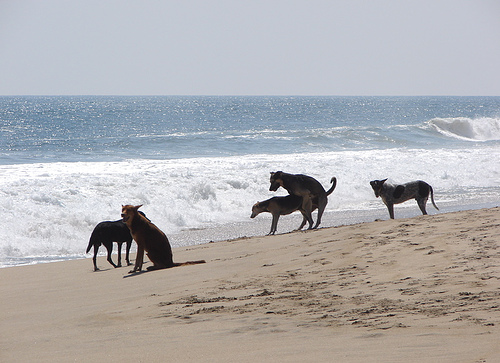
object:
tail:
[322, 177, 337, 198]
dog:
[263, 171, 337, 228]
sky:
[15, 3, 80, 82]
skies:
[92, 24, 105, 37]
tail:
[427, 185, 441, 211]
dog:
[368, 178, 440, 219]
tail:
[173, 259, 205, 268]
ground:
[0, 339, 19, 363]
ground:
[380, 248, 421, 265]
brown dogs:
[120, 203, 206, 273]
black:
[97, 230, 106, 238]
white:
[333, 155, 339, 159]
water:
[8, 155, 31, 166]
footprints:
[449, 312, 492, 324]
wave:
[0, 164, 27, 210]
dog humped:
[267, 171, 337, 229]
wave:
[480, 114, 499, 141]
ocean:
[5, 93, 499, 162]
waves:
[191, 129, 211, 141]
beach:
[0, 206, 500, 363]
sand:
[44, 270, 61, 281]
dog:
[85, 211, 152, 272]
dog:
[249, 194, 318, 233]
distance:
[5, 74, 495, 99]